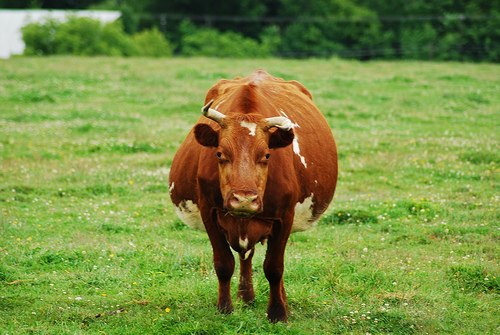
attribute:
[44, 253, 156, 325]
flowers — white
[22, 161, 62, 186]
flowers — white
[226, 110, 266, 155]
spot — white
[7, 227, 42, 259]
flowers — white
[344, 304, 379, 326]
flowers — growing 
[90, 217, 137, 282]
flower — yellow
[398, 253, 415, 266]
flower — Yellow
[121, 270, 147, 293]
flower — yellow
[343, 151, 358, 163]
flower — yellow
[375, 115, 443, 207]
flower — yellow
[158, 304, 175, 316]
flower — yellow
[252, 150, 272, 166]
eye — black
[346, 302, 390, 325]
flowers — white 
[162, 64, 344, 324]
bull — spots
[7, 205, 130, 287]
grass — green, lush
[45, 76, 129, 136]
flowers — white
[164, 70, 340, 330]
cow — whte, brown, white, brown and white, bloated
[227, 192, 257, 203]
nose — white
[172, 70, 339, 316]
cow — horn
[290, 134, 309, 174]
spot — white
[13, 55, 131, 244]
field — grassy